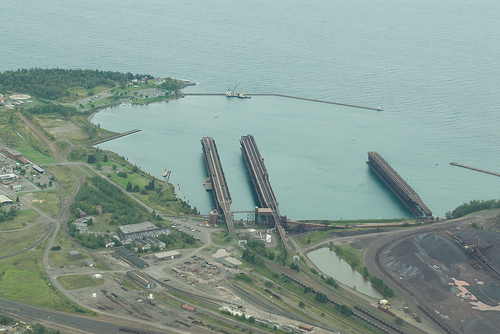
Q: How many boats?
A: Two.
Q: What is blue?
A: Water.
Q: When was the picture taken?
A: Daytime.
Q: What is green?
A: Grass.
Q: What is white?
A: Rooftops.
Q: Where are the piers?
A: In the water.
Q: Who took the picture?
A: Man.